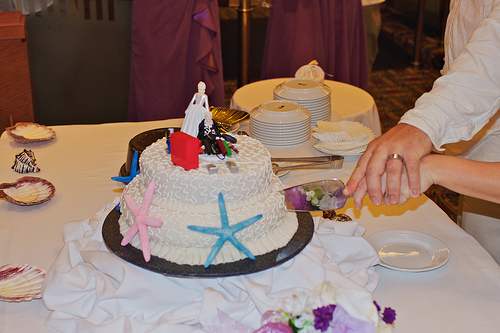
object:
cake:
[115, 131, 300, 267]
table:
[0, 115, 500, 333]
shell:
[3, 170, 59, 228]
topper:
[162, 81, 230, 157]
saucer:
[250, 100, 313, 125]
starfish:
[186, 191, 263, 269]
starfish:
[119, 176, 164, 263]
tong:
[271, 154, 345, 174]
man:
[340, 0, 499, 206]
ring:
[386, 154, 404, 163]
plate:
[273, 77, 333, 100]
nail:
[342, 186, 349, 194]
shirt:
[380, 0, 500, 155]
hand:
[337, 123, 430, 205]